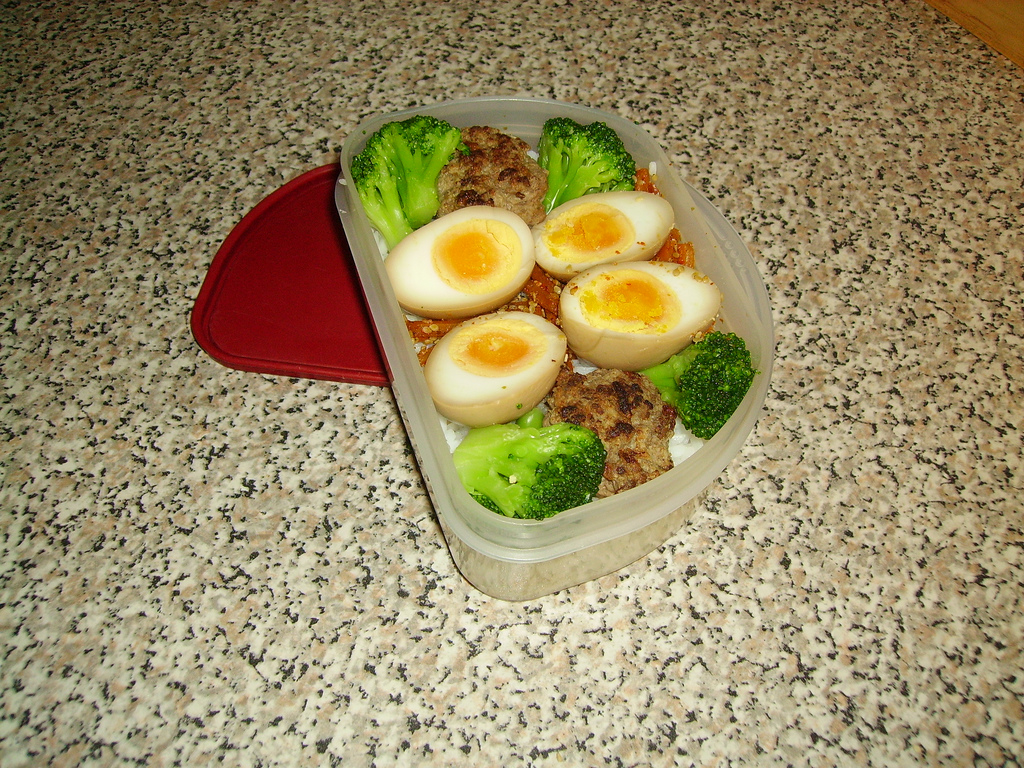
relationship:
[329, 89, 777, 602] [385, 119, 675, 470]
plastic container holding food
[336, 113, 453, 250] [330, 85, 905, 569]
broccoli in container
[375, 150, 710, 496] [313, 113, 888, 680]
food in container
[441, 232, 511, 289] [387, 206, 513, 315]
yellow part in potato slice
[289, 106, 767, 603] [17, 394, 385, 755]
container sitting on counter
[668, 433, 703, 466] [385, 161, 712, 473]
rice underneath food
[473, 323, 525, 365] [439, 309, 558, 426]
yolk in egg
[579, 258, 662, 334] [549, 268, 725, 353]
york in egg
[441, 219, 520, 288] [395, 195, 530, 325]
yellow part in egg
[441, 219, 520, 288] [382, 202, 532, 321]
yellow part in egg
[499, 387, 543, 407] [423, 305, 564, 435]
shell outside of egg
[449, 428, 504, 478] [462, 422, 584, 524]
stem on broccoli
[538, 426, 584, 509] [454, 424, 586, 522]
bush on broccoli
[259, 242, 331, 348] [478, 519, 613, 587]
lid for tupperware